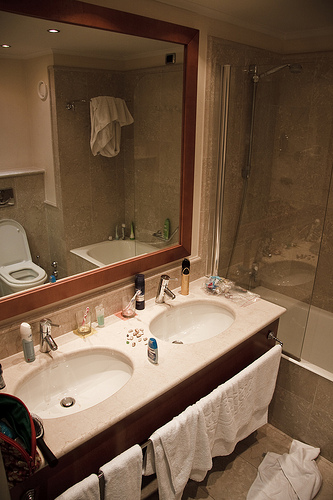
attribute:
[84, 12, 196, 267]
mirror — shining, clear, brown, large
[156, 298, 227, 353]
sink — white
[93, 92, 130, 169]
towel — white, hanging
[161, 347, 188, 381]
counter — white, grey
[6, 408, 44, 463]
bag — red, open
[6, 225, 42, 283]
toilet — white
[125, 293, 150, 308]
brush — blue, red